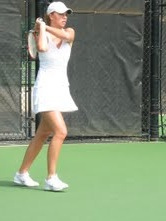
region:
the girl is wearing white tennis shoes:
[13, 161, 68, 200]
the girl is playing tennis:
[16, 3, 78, 145]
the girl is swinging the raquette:
[13, 14, 88, 63]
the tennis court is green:
[5, 148, 102, 217]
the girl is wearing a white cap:
[31, 0, 88, 24]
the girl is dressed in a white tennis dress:
[28, 27, 86, 127]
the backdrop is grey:
[76, 0, 141, 138]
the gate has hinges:
[149, 4, 162, 152]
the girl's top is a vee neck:
[29, 19, 93, 62]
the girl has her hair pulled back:
[31, 1, 74, 25]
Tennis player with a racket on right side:
[4, 0, 90, 202]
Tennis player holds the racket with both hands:
[20, 13, 47, 61]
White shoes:
[13, 171, 68, 195]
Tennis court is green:
[2, 141, 163, 219]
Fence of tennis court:
[73, 3, 163, 147]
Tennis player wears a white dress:
[11, 0, 84, 202]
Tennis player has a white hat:
[8, 0, 86, 198]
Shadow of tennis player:
[2, 173, 17, 193]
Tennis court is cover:
[75, 1, 147, 138]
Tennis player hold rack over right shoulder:
[7, 1, 90, 201]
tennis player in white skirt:
[20, 4, 90, 165]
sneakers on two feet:
[8, 167, 70, 191]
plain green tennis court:
[80, 156, 134, 193]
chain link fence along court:
[93, 103, 148, 136]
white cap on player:
[39, 0, 72, 18]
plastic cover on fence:
[81, 26, 145, 129]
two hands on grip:
[32, 15, 47, 31]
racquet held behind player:
[23, 25, 36, 63]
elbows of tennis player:
[38, 34, 70, 52]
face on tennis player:
[58, 11, 70, 26]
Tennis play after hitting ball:
[22, 3, 106, 60]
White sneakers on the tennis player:
[7, 169, 90, 203]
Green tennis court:
[72, 174, 114, 214]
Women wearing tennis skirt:
[37, 56, 106, 134]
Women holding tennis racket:
[11, 16, 71, 67]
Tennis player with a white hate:
[38, 2, 140, 62]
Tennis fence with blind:
[102, 12, 157, 34]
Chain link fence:
[147, 8, 162, 43]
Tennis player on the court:
[3, 7, 87, 213]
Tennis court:
[21, 164, 148, 213]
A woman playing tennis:
[29, 4, 95, 136]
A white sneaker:
[43, 171, 68, 197]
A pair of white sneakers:
[9, 165, 71, 192]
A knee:
[51, 125, 71, 143]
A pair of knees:
[25, 123, 73, 141]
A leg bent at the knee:
[45, 113, 71, 192]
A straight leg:
[19, 121, 49, 193]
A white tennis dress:
[33, 27, 92, 133]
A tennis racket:
[23, 15, 43, 58]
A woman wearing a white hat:
[35, 3, 81, 26]